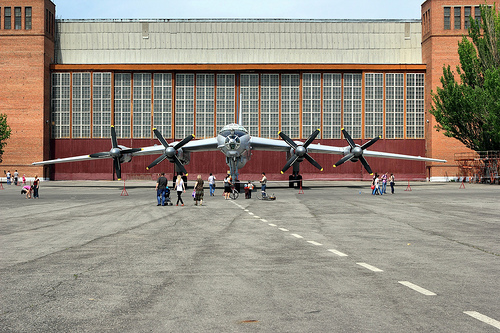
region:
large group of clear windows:
[76, 81, 118, 131]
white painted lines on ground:
[339, 241, 404, 309]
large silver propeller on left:
[91, 119, 154, 189]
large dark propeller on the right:
[341, 131, 389, 181]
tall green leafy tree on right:
[469, 40, 496, 117]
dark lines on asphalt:
[191, 225, 245, 285]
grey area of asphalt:
[68, 222, 93, 240]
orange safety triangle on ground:
[405, 176, 417, 210]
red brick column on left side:
[6, 59, 35, 104]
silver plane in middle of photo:
[62, 123, 440, 200]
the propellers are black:
[86, 110, 422, 216]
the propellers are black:
[57, 83, 424, 173]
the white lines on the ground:
[230, 200, 383, 285]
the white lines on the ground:
[293, 215, 370, 289]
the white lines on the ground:
[326, 237, 438, 329]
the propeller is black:
[270, 127, 306, 155]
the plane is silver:
[251, 136, 276, 148]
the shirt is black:
[158, 178, 166, 186]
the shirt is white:
[176, 182, 185, 189]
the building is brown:
[11, 93, 33, 123]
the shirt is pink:
[24, 183, 31, 192]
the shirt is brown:
[196, 179, 203, 189]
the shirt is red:
[32, 179, 39, 188]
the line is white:
[324, 244, 350, 261]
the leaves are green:
[448, 89, 482, 121]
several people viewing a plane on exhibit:
[86, 133, 277, 217]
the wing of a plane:
[252, 131, 455, 173]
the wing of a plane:
[28, 127, 213, 177]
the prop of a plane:
[335, 127, 381, 174]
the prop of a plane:
[270, 123, 325, 178]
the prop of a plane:
[141, 125, 198, 175]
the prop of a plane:
[81, 128, 143, 180]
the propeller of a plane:
[335, 122, 380, 177]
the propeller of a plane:
[275, 125, 326, 177]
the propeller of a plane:
[144, 124, 196, 179]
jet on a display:
[27, 120, 452, 197]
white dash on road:
[328, 242, 344, 262]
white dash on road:
[352, 255, 378, 275]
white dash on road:
[396, 273, 441, 303]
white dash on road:
[282, 230, 304, 241]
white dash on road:
[263, 220, 274, 230]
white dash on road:
[255, 215, 263, 220]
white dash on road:
[251, 211, 266, 221]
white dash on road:
[455, 300, 483, 330]